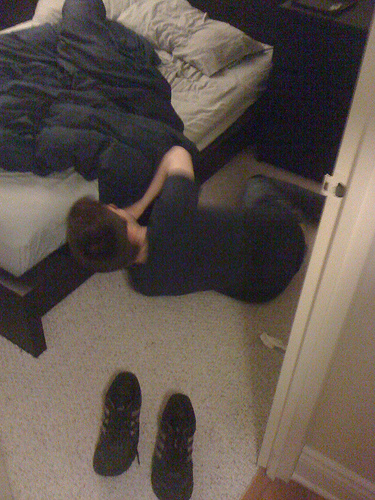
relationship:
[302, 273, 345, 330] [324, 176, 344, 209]
door has plate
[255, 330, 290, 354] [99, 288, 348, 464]
paper on floor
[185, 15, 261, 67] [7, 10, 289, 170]
pillowcase on bed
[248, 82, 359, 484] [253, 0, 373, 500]
door has door frame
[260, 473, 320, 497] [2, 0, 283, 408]
wood floor outside bedroom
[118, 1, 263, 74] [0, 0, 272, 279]
white pillowcase on top of bed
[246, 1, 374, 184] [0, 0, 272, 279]
nightstand on side of bed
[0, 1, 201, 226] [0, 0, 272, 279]
blanket lying on bed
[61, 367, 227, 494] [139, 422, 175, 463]
shoes with stripes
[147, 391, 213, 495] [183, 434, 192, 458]
shoe with stripe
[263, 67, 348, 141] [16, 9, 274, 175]
drawer next to bed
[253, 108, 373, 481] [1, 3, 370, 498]
door frame to bedroom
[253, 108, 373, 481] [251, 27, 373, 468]
door frame to door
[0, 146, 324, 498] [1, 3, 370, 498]
bedroom carpet in bedroom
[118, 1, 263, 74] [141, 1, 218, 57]
white pillowcase in white pillowcase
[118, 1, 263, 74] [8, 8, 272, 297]
white pillowcase on right side of bed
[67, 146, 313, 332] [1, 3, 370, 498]
boy in bedroom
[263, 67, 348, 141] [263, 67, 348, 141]
drawer built into drawer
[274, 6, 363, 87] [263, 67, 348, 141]
drawer built into drawer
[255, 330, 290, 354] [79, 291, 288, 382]
paper on floor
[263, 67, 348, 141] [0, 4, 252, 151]
drawer near bed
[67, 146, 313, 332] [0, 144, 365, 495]
boy on floor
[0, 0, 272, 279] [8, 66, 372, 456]
bed in bedroom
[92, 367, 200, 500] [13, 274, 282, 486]
shoes on carpet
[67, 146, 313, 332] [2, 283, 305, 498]
boy on floor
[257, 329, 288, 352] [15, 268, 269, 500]
elephant on carpet